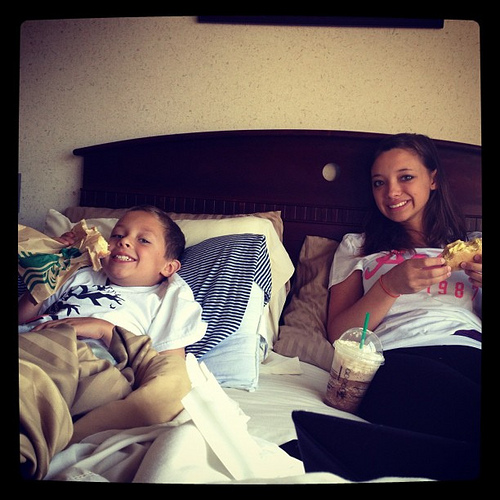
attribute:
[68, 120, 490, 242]
headboard — rounded, brown colored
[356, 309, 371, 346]
straw — green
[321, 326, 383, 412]
drink — brown, white, dessert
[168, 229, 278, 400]
pillow — white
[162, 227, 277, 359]
pillow case — black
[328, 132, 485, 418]
woman — smiling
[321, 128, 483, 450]
girl — teenager, smiling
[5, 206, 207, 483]
young boy — smiling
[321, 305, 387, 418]
drink — coffee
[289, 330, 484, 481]
pants — black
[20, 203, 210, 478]
boy — smiling, young